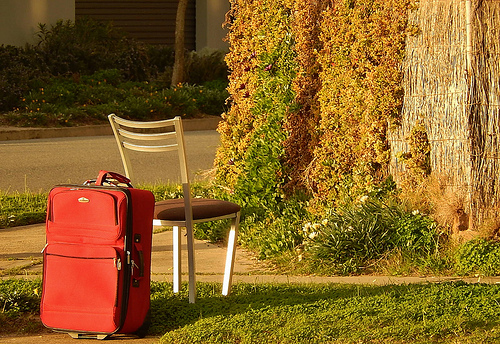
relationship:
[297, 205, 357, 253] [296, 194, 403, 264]
flowers growing from grass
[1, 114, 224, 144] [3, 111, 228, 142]
curb of sidewalk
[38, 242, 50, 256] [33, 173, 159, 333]
silver zipper on suitcase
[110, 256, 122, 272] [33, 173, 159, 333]
silver zipper on suitcase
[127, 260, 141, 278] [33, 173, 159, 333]
silver zipper on suitcase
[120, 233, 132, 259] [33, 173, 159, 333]
silver zipper on suitcase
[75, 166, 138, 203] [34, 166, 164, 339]
handle on suitcase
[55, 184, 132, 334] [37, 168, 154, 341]
zipper on suitcase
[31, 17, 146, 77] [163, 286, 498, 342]
bush on grass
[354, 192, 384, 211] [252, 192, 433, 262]
flowers on grass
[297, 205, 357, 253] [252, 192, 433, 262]
flowers on grass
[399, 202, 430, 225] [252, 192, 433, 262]
flowers on grass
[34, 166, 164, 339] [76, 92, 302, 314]
suitcase behind chair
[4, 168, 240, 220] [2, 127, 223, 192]
curb on street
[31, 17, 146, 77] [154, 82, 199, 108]
bush behind flowers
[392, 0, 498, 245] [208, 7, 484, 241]
trunk on tree